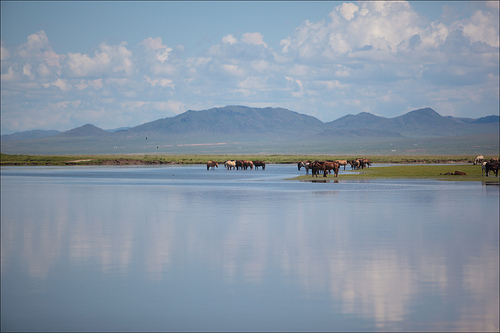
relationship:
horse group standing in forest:
[204, 158, 372, 183] [43, 144, 476, 167]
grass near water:
[328, 137, 457, 193] [256, 168, 381, 288]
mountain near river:
[170, 77, 457, 204] [2, 165, 453, 331]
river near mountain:
[0, 164, 499, 331] [2, 100, 499, 152]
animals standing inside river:
[204, 154, 278, 169] [106, 174, 305, 286]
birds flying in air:
[142, 132, 164, 152] [2, 3, 496, 150]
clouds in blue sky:
[2, 0, 497, 132] [4, 2, 259, 39]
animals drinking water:
[204, 158, 268, 171] [275, 192, 372, 299]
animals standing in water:
[204, 158, 268, 171] [36, 150, 470, 311]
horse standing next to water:
[308, 156, 328, 177] [36, 150, 470, 311]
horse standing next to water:
[323, 159, 339, 176] [36, 150, 470, 311]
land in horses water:
[0, 105, 499, 182] [198, 156, 376, 193]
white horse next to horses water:
[467, 153, 487, 165] [198, 156, 376, 193]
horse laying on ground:
[481, 154, 498, 189] [368, 162, 488, 182]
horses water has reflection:
[198, 156, 376, 193] [1, 199, 498, 324]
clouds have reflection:
[2, 0, 497, 132] [1, 199, 498, 324]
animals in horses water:
[204, 158, 268, 171] [198, 156, 376, 193]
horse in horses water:
[323, 159, 339, 178] [198, 156, 376, 193]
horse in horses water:
[333, 154, 353, 169] [198, 156, 376, 193]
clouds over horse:
[2, 0, 497, 132] [310, 160, 327, 177]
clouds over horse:
[2, 0, 497, 132] [202, 159, 219, 170]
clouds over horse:
[2, 0, 497, 132] [333, 159, 350, 169]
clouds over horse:
[2, 0, 497, 132] [348, 159, 360, 168]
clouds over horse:
[2, 0, 497, 132] [251, 154, 266, 170]